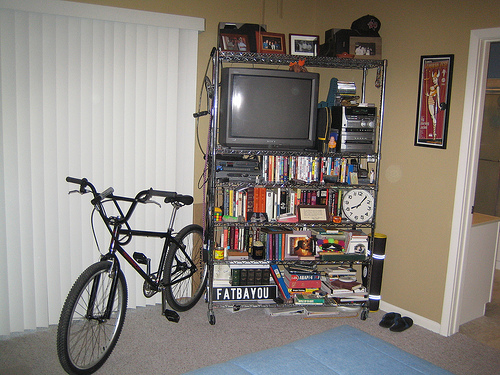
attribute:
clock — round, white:
[343, 186, 373, 222]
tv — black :
[228, 80, 318, 151]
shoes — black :
[379, 307, 414, 330]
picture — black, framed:
[413, 47, 457, 154]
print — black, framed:
[404, 52, 456, 165]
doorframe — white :
[440, 23, 497, 350]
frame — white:
[402, 15, 497, 345]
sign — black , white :
[207, 280, 283, 308]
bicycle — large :
[51, 176, 206, 371]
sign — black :
[210, 272, 265, 314]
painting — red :
[408, 43, 462, 162]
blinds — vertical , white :
[1, 1, 205, 333]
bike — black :
[43, 174, 220, 374]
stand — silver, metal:
[199, 48, 389, 320]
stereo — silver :
[326, 103, 380, 153]